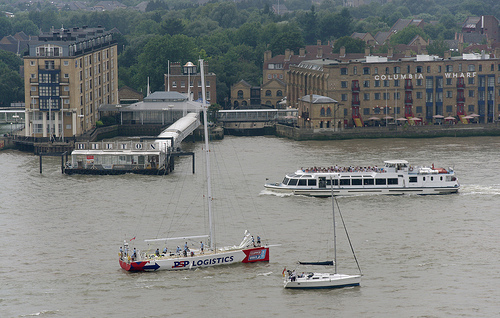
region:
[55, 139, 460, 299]
Three boats in the water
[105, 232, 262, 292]
A red and white boat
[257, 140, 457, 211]
A boat with people on top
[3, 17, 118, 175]
Building in the background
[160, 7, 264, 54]
Trees behind the buildings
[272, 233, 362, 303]
A small white boat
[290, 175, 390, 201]
the boat has a lot of windows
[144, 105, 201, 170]
A bridge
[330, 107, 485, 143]
A patio to sit outside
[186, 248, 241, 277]
The boat reads "logistics"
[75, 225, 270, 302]
Red and white boat.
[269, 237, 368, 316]
Blue and white boat.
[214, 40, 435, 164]
bUILDING BU THE WATER.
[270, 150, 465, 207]
Large boat with a group of people on it.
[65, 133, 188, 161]
Sign that saya HILTON.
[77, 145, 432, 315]
Three boats in the water.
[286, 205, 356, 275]
Sail on a sail boat rolled down.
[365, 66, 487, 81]
Sign that says COLUMBIA WHARF.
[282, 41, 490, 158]
LARGE HOTEL ON THE WATER.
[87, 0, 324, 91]
LOTS OF OF TREES BEHIND BUILDINGS.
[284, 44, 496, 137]
Columbia Wharf warehouse buildings.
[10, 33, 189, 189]
Hilton Hotel docking area.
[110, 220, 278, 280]
Logistics sail boat manned workers.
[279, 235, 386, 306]
Small boat skims waterfront.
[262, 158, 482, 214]
Passenger ferry fully loaded people.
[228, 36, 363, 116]
Additional outer buildings belong wharf.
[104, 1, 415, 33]
Background completely wooded area.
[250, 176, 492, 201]
Small waves show boat movement.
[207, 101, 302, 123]
Pedestrian walk way wharf hotel.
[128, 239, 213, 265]
At least four shipmates work.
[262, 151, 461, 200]
Large white boat carrying many passengers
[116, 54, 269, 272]
Medium red and white boat with about ten people in it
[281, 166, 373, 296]
Small white boat with one person in it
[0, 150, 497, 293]
Lake which contains all three boats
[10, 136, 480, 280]
Lake along a city side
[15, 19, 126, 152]
tall building on the lake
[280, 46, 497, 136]
A building on the lake name Columbia Wharf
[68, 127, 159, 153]
Sign that says HILTON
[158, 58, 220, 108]
A small red brick building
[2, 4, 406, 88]
Trees surrounding the city side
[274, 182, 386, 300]
a small white and blue sailboat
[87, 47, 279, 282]
a large red and white boat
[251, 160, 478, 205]
a large white yacht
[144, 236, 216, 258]
a group of people in blue shirts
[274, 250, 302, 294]
a flag on end of boat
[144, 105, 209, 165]
a covered walkway and bridge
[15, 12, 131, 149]
a large, old building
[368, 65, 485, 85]
a company name display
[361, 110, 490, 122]
a few tan umbrellas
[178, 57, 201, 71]
a shiny copper dome